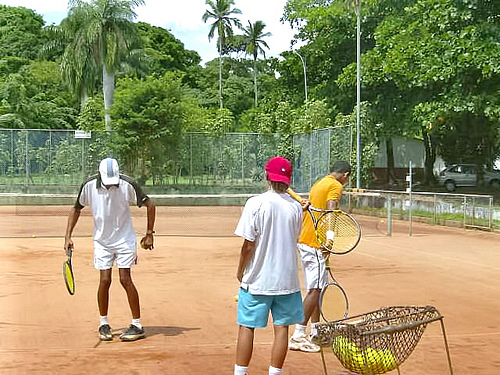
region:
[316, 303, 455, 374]
A basket full of tennis balls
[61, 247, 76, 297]
A black and yellow tennis racket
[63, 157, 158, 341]
A male tennis player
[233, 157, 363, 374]
A boy holding a tennis racket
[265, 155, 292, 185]
A red baseball cap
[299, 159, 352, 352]
A boy in a yellow shirt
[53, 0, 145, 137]
A palm tree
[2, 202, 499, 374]
A dirt tennis court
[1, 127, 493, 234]
A chain link fence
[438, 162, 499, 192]
A parked car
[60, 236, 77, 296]
Holding the racket in the right hand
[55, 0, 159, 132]
Palm tree in the background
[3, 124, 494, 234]
Fences around the perimeter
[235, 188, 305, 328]
White shirt and blue shorts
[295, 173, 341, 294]
Yellow shirt and white shorts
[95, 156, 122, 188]
Blue stripe on top of cap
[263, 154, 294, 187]
Wearing a red cap backwards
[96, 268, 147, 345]
Skinny legs and toeing in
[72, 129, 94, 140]
Sign hanging on the fence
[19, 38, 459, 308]
this is a tennis court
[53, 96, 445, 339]
the people are playing tennis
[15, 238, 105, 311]
this is a tennis racket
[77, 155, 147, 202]
the man is wearing a hat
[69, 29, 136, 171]
this is a palm tree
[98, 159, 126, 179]
the man's hat is gray and white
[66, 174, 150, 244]
the man's shirt is black and white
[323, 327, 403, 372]
these are tennis balls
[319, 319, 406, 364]
the tennis balls are yellow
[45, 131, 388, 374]
three people playing tennis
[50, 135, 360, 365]
three people with tennis racquets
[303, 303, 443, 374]
tennis balls in a basket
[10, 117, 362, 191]
a fence at a tennis court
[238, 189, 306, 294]
a person wearing a white shirt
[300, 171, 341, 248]
a person wearing an orange shirt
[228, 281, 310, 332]
a person wearing blue shorts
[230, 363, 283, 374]
a person wearing white socks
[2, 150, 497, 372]
Three people standing on a tennis court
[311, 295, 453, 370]
Tennis balls in a basket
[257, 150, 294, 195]
Red hat on person's head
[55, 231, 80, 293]
Tennis racket in a hand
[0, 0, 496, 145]
Green leaves on many trees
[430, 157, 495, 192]
A car is gray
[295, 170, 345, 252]
A yellow colored shirt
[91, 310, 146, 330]
A pair of white socks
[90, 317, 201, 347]
A man's shadow on the tennis court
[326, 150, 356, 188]
Man has black hair